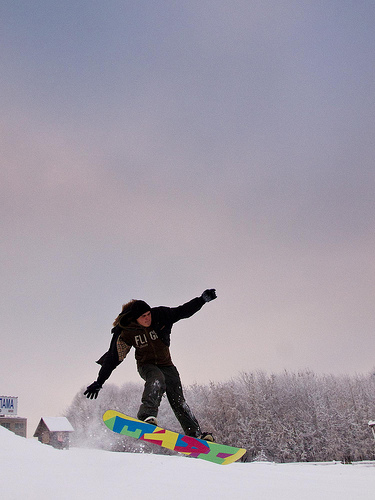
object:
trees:
[228, 364, 336, 446]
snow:
[195, 279, 224, 454]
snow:
[71, 436, 177, 491]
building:
[32, 416, 74, 450]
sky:
[219, 222, 325, 319]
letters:
[0, 395, 18, 418]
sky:
[47, 56, 259, 226]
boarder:
[83, 288, 217, 442]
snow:
[45, 393, 145, 481]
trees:
[260, 369, 352, 456]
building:
[0, 394, 27, 438]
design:
[102, 410, 247, 466]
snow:
[50, 441, 186, 483]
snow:
[74, 450, 203, 477]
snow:
[58, 440, 139, 491]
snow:
[62, 423, 181, 495]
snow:
[64, 440, 164, 488]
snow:
[102, 406, 246, 483]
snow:
[76, 447, 234, 491]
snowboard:
[102, 410, 247, 465]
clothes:
[95, 295, 206, 389]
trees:
[170, 365, 375, 463]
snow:
[217, 381, 367, 461]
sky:
[0, 0, 375, 391]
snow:
[55, 424, 132, 477]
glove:
[83, 381, 102, 399]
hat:
[131, 300, 152, 320]